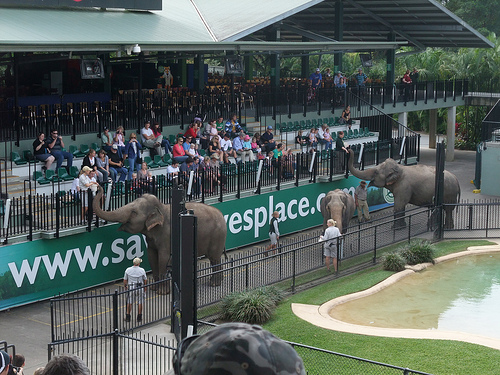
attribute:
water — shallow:
[328, 255, 483, 342]